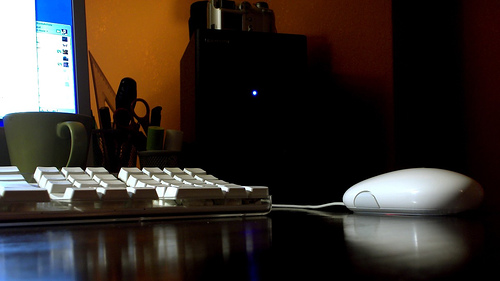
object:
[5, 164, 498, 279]
desk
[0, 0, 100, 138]
screen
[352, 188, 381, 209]
button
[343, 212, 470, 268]
reflection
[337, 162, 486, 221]
mouse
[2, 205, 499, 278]
table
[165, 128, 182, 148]
highlighter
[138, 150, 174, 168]
cup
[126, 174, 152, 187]
key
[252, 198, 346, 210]
cord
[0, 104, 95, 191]
mug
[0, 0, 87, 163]
computer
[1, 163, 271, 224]
keyboard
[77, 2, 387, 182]
wall